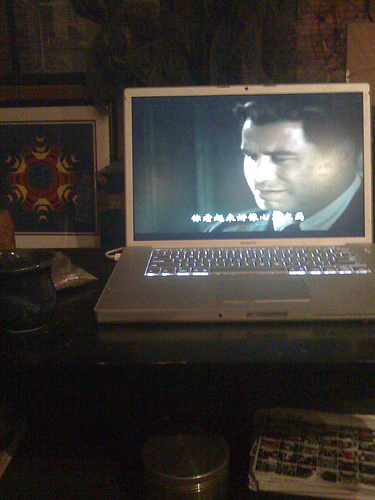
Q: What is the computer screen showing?
A: A movie.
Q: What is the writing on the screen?
A: Chinese.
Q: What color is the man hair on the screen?
A: Black.